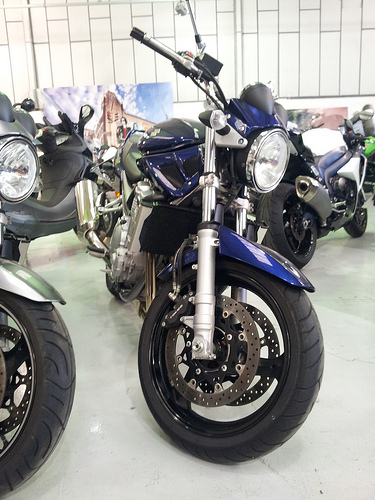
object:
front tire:
[0, 289, 78, 497]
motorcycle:
[1, 88, 117, 500]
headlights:
[253, 126, 289, 195]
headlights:
[0, 138, 39, 203]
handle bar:
[127, 0, 231, 116]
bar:
[20, 0, 43, 88]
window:
[1, 3, 374, 100]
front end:
[130, 2, 325, 465]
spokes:
[179, 344, 284, 382]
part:
[218, 264, 326, 465]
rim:
[148, 272, 289, 437]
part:
[223, 270, 290, 436]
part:
[322, 274, 374, 499]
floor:
[326, 236, 375, 498]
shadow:
[105, 294, 179, 451]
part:
[125, 349, 168, 438]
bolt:
[224, 331, 234, 341]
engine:
[103, 218, 146, 297]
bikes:
[353, 100, 374, 185]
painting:
[39, 82, 177, 160]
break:
[144, 32, 201, 74]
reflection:
[229, 231, 270, 266]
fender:
[218, 223, 314, 295]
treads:
[85, 239, 108, 261]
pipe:
[75, 177, 109, 254]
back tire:
[344, 203, 369, 237]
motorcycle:
[260, 115, 373, 267]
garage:
[1, 0, 372, 495]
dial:
[201, 52, 224, 75]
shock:
[143, 256, 157, 309]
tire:
[138, 256, 326, 464]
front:
[131, 21, 326, 472]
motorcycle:
[85, 0, 330, 465]